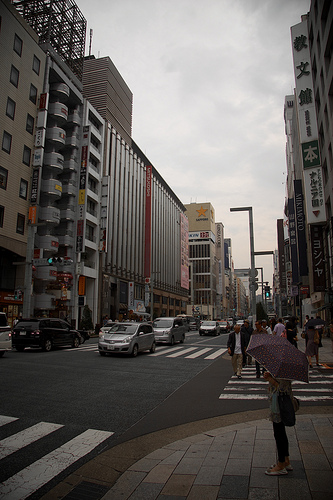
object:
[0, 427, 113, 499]
line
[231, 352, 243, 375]
pants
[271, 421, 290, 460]
pants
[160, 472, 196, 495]
bricks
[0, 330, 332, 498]
ground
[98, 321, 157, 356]
cars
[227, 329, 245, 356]
coat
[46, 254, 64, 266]
signal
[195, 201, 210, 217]
star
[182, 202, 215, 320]
building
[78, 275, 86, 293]
sign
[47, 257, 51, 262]
light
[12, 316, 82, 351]
vehicle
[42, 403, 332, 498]
walkway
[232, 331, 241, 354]
shirt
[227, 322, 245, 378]
man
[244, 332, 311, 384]
umbrella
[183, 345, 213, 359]
lines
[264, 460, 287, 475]
shoes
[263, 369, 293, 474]
person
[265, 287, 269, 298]
signal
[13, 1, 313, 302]
sky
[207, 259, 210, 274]
window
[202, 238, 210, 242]
window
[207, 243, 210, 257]
window